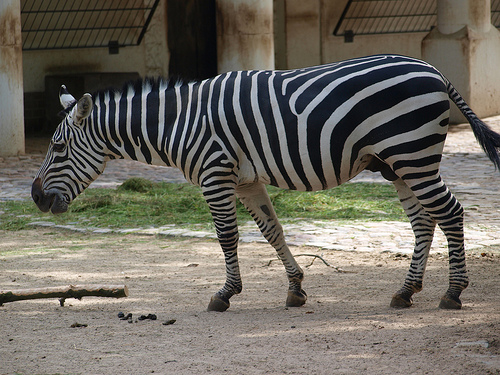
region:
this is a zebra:
[38, 83, 484, 320]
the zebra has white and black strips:
[247, 93, 326, 160]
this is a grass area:
[116, 180, 173, 210]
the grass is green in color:
[115, 188, 163, 211]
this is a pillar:
[218, 16, 289, 76]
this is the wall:
[288, 23, 337, 47]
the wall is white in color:
[288, 24, 330, 56]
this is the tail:
[453, 91, 493, 134]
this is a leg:
[211, 165, 247, 272]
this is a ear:
[71, 89, 95, 121]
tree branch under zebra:
[0, 283, 127, 306]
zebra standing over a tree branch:
[29, 53, 499, 312]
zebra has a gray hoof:
[206, 296, 229, 312]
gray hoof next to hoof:
[287, 294, 306, 306]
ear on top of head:
[73, 93, 94, 118]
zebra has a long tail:
[448, 82, 498, 171]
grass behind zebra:
[2, 178, 409, 228]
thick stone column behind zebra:
[215, 0, 275, 74]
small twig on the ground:
[293, 252, 333, 273]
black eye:
[52, 142, 65, 151]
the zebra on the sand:
[21, 53, 486, 343]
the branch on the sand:
[5, 276, 140, 326]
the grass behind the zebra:
[88, 175, 197, 230]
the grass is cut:
[106, 172, 198, 222]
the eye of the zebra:
[48, 138, 75, 160]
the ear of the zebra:
[70, 91, 99, 124]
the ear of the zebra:
[47, 83, 74, 105]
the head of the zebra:
[21, 73, 128, 217]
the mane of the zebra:
[71, 72, 190, 97]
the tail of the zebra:
[440, 81, 499, 151]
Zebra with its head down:
[12, 76, 117, 222]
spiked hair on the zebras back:
[84, 83, 178, 98]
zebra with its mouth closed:
[30, 177, 72, 223]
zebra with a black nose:
[16, 173, 76, 219]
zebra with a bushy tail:
[446, 86, 492, 151]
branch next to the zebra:
[12, 278, 139, 323]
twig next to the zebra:
[271, 230, 358, 287]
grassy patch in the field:
[87, 174, 384, 233]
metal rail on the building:
[24, 5, 149, 55]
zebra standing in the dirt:
[100, 89, 468, 333]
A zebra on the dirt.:
[29, 51, 498, 312]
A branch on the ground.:
[0, 281, 131, 308]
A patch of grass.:
[0, 174, 412, 233]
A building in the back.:
[3, 1, 498, 158]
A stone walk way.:
[0, 117, 498, 263]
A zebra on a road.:
[30, 52, 499, 312]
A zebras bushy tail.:
[448, 79, 499, 170]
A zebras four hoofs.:
[206, 287, 463, 314]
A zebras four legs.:
[200, 181, 470, 313]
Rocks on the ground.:
[116, 308, 175, 326]